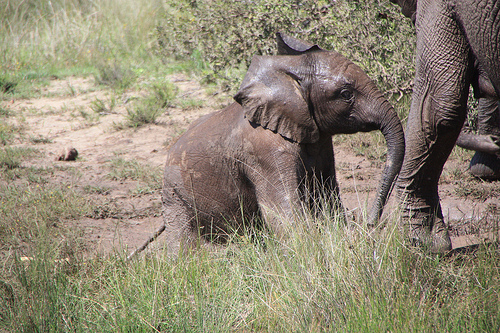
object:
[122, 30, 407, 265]
elephant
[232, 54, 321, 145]
ear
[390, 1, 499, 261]
elephant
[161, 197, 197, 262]
hind leg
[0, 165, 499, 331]
grass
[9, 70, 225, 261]
dirt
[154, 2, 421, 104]
bush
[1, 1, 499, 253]
ground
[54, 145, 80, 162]
rock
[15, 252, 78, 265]
branch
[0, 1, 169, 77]
grass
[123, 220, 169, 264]
tail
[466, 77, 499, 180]
left leg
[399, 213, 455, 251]
foot